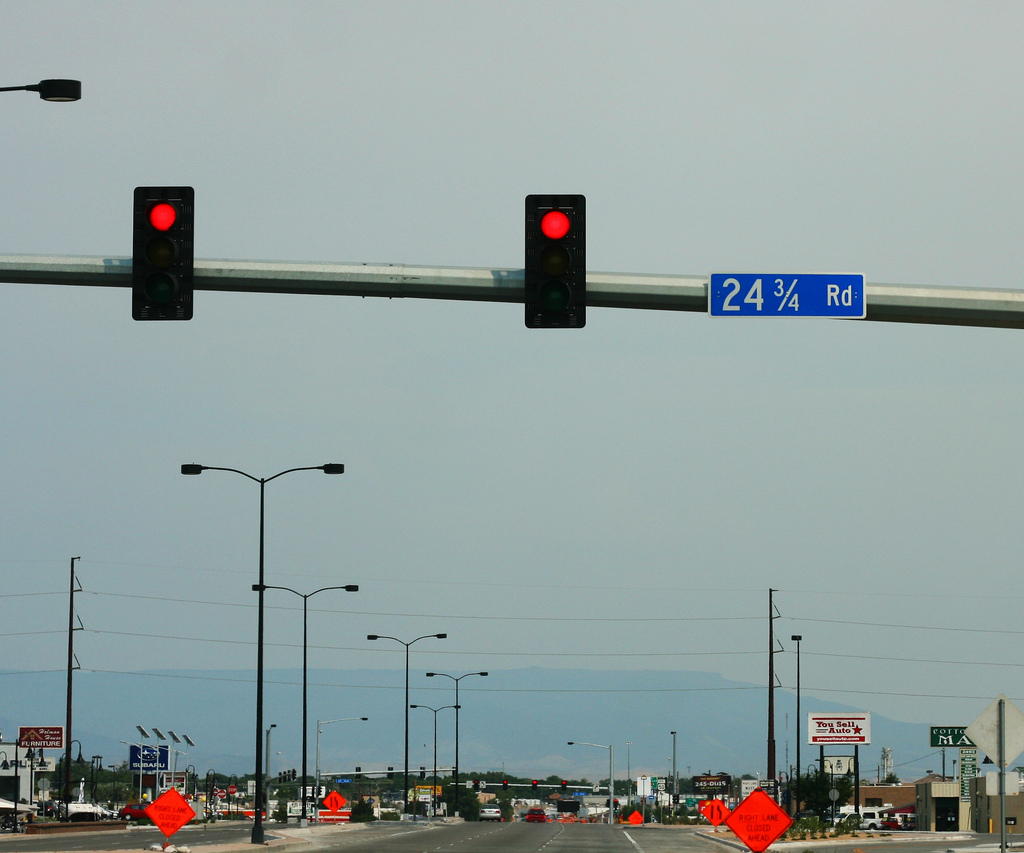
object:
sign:
[709, 272, 867, 321]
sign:
[807, 711, 872, 744]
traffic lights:
[525, 192, 588, 328]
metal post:
[0, 255, 1022, 332]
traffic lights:
[131, 185, 194, 321]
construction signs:
[147, 786, 197, 837]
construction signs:
[723, 785, 795, 852]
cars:
[526, 808, 546, 822]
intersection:
[454, 773, 623, 852]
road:
[228, 820, 743, 851]